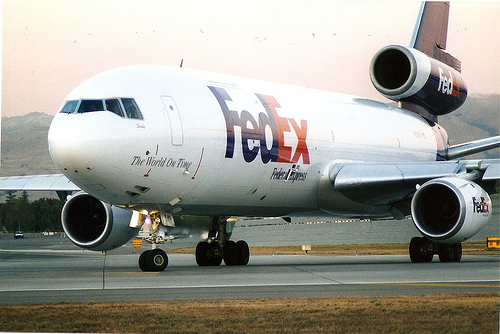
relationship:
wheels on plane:
[201, 237, 251, 260] [58, 61, 466, 205]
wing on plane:
[361, 159, 495, 236] [58, 61, 466, 205]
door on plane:
[154, 101, 191, 143] [58, 61, 466, 205]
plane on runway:
[58, 61, 466, 205] [300, 249, 356, 282]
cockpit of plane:
[74, 89, 132, 122] [58, 61, 466, 205]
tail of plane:
[404, 7, 461, 119] [58, 61, 466, 205]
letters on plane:
[211, 86, 319, 166] [58, 61, 466, 205]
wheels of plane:
[201, 237, 251, 260] [58, 61, 466, 205]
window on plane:
[120, 99, 145, 121] [58, 61, 466, 205]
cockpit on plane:
[74, 89, 132, 122] [58, 61, 466, 205]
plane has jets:
[58, 61, 466, 205] [6, 0, 499, 266]